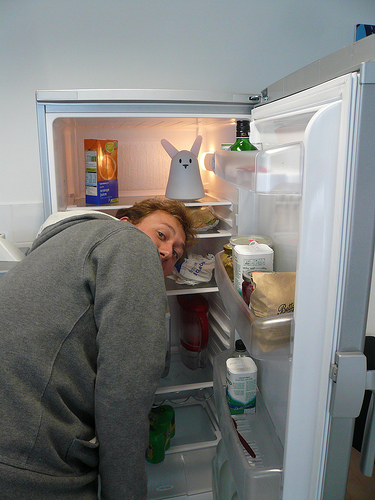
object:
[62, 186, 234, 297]
shelf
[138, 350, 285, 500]
shelf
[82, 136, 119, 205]
orange juice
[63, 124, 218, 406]
back wall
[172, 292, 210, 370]
pitcher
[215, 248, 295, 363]
items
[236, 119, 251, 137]
bottle lid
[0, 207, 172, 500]
jacket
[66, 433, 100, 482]
pocket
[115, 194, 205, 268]
hair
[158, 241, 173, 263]
nose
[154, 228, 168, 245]
eyes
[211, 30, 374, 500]
refrigerator door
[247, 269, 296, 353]
bag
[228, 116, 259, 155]
bottle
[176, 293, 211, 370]
canister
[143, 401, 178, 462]
soda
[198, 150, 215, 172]
light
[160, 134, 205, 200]
cat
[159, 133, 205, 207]
rabbit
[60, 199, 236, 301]
edge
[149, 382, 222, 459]
drawer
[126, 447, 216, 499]
bottom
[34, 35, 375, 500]
fridge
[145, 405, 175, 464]
pack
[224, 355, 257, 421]
milk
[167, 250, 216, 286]
bag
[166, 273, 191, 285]
spoon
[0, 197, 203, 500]
boy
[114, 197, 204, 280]
head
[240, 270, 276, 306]
container